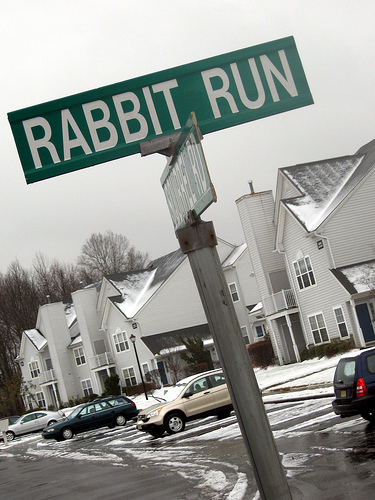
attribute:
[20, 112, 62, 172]
letter — white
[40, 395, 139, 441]
car — parked, dark colored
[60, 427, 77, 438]
tire — rubber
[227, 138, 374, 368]
building — in a row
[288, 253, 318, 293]
window — second story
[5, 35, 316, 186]
sign — green, slanted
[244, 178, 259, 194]
chimney — vertical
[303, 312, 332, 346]
window — double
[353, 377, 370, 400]
brake light — rear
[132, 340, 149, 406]
pole — short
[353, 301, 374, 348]
front door — blue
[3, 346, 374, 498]
ground — gray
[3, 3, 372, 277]
sky — gray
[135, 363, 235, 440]
car — brown, gold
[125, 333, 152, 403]
street light — black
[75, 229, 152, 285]
trees — leafless, bare